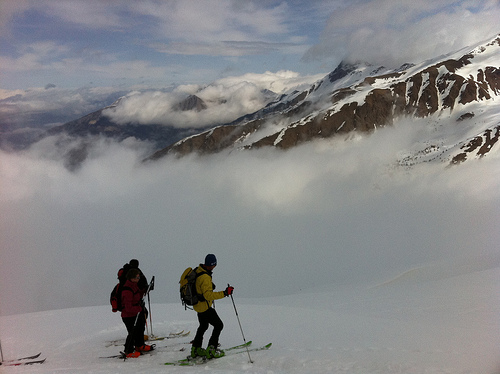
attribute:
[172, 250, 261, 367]
man — skiing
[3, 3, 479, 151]
sky — open, big, blue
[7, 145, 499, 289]
clouds — big, white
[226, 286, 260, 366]
ski pole — long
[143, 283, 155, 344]
ski pole — long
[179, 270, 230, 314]
coat — yellow